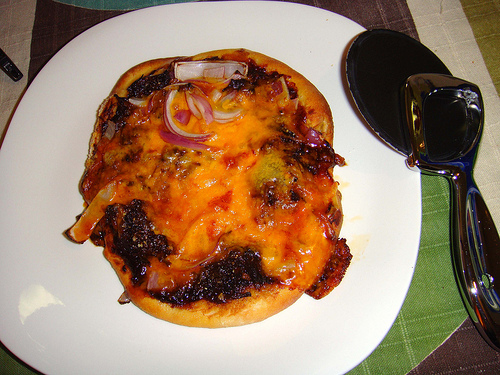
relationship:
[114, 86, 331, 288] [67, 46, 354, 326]
cheese on food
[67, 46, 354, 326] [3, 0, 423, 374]
food on plate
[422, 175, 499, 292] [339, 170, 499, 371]
pattern on placemat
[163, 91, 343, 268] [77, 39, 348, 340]
cheese on pizza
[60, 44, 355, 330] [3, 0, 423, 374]
pizza on plate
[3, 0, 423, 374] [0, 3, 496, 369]
plate on table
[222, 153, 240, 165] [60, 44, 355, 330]
sauce on pizza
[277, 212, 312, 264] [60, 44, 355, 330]
sauce on pizza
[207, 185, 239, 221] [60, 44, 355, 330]
sauce on pizza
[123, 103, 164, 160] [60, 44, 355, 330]
sauce on pizza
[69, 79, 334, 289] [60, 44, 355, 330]
sauce on pizza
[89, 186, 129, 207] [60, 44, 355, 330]
sauce on pizza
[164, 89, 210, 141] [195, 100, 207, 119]
onion on onion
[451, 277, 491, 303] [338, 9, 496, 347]
light on utensil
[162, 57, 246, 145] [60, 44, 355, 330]
onions on pizza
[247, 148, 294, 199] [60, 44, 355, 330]
spot on pizza